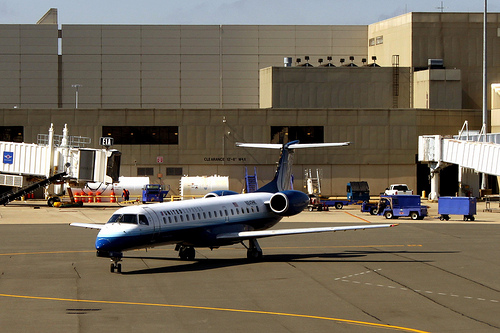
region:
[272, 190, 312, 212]
a passenger jet engine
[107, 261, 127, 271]
wheels on a plane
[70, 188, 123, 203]
a row of orange traffic cones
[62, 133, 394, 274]
a long passenger plane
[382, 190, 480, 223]
a blue cart pulling a container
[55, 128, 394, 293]
a passenger plane on the tarmac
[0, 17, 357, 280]
a plane at the airport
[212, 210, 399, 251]
the wing of a passenger plane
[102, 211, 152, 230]
the front windshield of a passenger plane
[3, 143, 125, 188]
the loading bridge to a plane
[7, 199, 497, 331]
plane on darker side of tan and brown ground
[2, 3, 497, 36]
bright solid blue sky over flat roof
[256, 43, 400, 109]
long container with angled contents and raised poles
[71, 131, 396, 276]
blue and white plane in front of building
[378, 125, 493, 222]
elevated tunnel over blue service vehicles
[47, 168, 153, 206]
man and orange cones in front of white tank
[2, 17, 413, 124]
platform on top of building roof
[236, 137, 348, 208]
ladders leaning against wall under tail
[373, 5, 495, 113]
small boxy structure in front of larger boxy structure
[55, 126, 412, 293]
airplane on the tarmac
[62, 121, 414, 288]
blue and white plane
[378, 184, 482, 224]
blue trailer being pulled by a blue vehicle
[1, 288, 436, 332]
yellow line on the ground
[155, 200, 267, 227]
small windows on the side of the plane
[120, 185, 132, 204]
person on the tarmac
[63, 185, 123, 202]
orange and white cones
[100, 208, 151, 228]
windows around the cockpit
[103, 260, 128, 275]
a pair of wheels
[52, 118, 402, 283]
this is an airplane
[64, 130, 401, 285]
this is a small plane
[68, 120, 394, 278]
a blue and white airplane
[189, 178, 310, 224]
the engines are mounted on the rear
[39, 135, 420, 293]
the plane is on the tarmac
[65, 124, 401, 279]
the plane is on the ground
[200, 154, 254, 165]
this is text on the wall that signifies height clearances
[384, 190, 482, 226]
these are blue luggage carts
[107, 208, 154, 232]
this is the front windshield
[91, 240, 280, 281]
this is the landing gear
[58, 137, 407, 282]
airplane parked on tarmac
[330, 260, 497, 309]
white lines on tarmac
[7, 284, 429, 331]
yellow line on tarmac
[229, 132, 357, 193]
tail of airplane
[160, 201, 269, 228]
windows on side of airplane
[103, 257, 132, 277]
wheels on bottom of plane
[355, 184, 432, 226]
service vehicle on tarmac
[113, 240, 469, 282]
shadow of plane on tarmac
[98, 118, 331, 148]
windows on side of stone building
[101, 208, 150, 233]
windshield on front of plane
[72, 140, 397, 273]
blue and white airplane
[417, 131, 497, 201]
white passenger boarding tube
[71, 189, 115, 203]
five orange and white safety barrels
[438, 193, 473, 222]
blue luggage trailer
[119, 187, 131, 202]
worker in orange safety vest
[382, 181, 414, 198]
parked white truck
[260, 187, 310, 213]
jet is at the side of the airplane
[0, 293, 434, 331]
yellow line is on the run way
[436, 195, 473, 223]
blue cart is at the side of the runway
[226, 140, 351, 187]
tail is at the back of the plane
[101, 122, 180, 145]
window is apart of building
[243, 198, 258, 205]
writing is blue